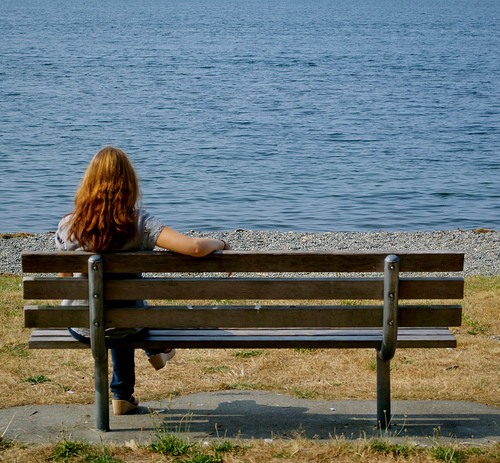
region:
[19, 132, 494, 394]
a woman sitting on a bench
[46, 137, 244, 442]
the back of a woman on a bench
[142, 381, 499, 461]
shadow of bench on ground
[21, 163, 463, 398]
a bench by the water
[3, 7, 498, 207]
calm blue water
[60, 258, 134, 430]
metal pole that supports bench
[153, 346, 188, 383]
wedge sandals on feet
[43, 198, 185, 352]
a woman in a gray top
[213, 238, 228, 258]
a watch on her wrist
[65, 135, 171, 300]
long brown hair on woman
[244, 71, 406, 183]
Blue rippling water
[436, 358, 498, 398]
Dry green grass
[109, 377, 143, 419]
The heels of shoes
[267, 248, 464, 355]
The back of a wooden bench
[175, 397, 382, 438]
A shadow of the bench and a woman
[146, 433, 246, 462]
Patches of green grass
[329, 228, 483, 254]
Gray slate granite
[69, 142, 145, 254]
The back of a woman's long red hair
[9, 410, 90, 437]
A gray asphalt ground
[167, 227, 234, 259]
The arm and elbow of a person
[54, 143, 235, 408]
A girl with long hair and blue jeans sitting on a bench.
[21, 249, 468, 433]
Brown wood and silver metal bench.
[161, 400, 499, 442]
Dark grey shadow of the woman and the bench.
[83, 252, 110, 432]
metal rail holding together the bench behind a woman's head.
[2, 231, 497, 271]
Gravel on the ground in front of a bench.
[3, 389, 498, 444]
Grey sidewalk around a bench.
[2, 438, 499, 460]
Brown and green grass behind a bench.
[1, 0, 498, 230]
A large amount of blue water.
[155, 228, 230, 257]
The right arm of a woman on a bench.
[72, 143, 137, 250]
The reddish tinted long hair of a sitting woman.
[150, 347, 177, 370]
part of a woman's shoe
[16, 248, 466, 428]
a large wooden bench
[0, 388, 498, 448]
a concrete slab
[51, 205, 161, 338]
a woman's gray shirt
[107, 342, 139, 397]
part of a woman's leg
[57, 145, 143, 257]
part of a woman's long hair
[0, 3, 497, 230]
a large body of water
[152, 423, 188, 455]
a small section of grass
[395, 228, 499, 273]
a section of rocks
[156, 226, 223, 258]
the arm of a woman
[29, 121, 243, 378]
a woman sitting on the bench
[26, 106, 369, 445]
a woman sitting on the bench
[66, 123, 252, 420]
woman is watching the water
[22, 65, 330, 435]
woman is watching the water